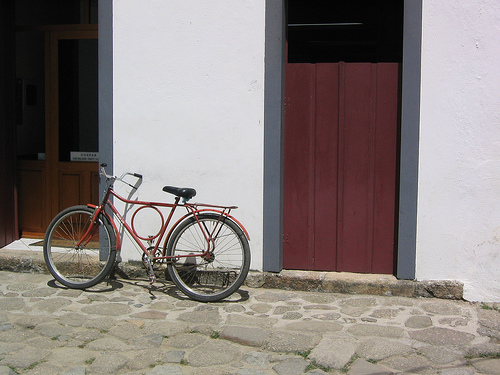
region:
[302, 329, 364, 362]
gray stone on ground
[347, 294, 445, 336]
white lines on the ground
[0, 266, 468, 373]
large section of gray and white cobble stones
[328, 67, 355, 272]
solid bold lines on brown door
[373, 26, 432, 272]
gray edges at side of door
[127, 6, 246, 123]
gray walls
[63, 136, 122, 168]
large white name plate on door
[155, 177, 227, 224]
black shiny bicycle seat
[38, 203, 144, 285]
large black bicycle seat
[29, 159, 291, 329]
red bike at front of building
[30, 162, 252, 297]
this is a bicycle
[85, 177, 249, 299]
the bicycle is close to the wall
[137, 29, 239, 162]
this is a building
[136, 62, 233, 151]
the wall is white in color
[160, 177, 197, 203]
this is a bicycle seat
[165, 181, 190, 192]
the seat is black in color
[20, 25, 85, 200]
this is a door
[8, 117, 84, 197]
the door is closed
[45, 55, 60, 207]
the door is made of wood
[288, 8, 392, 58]
space above the door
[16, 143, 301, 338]
red bike leaning against a building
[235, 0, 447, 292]
red wooden door with grey trim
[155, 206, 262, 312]
large rubber bike tire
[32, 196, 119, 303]
large rubber bike tire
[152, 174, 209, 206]
black leather bike seat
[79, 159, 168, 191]
silver and black bicycle handle bars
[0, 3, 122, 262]
brown door with grey trim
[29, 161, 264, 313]
red bike leaning against white wall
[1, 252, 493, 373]
grey stone road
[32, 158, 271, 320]
red bike with silver handle bars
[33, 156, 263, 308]
bike sitting against wall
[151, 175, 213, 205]
black seat of bike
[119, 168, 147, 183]
bike handlebar against wall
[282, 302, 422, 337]
stones in cement on sidewalk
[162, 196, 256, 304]
rear wheel of bike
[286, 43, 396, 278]
red door on building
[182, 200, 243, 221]
rack on back of bike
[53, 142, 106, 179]
sign in door widow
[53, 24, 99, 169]
glass in wood door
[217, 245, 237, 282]
spokes in bike wheel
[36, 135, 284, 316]
a red bicycle next to a wall.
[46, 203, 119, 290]
front wheel of a bicycle.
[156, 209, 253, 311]
rear wheel of a bicycle.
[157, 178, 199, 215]
black seat on a bicycle.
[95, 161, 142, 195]
handle bars of a bicycle.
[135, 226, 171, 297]
pedal area of a bicycle.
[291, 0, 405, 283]
a brown doorway area.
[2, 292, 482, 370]
gray stone travel area.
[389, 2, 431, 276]
gray door frame area.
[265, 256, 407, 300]
stone step entrance area.